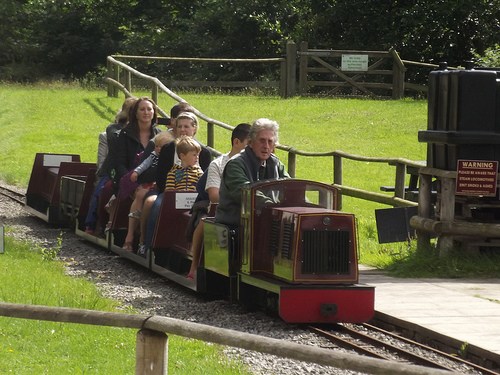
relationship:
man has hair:
[216, 118, 307, 225] [249, 117, 279, 146]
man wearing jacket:
[216, 118, 307, 225] [216, 150, 301, 220]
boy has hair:
[162, 136, 205, 192] [175, 136, 202, 159]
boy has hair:
[129, 132, 176, 182] [154, 131, 177, 148]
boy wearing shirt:
[129, 132, 176, 182] [134, 151, 162, 172]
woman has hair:
[145, 113, 214, 256] [175, 111, 199, 137]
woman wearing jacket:
[145, 113, 214, 256] [155, 140, 212, 194]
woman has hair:
[117, 98, 165, 177] [129, 97, 158, 132]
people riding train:
[83, 97, 291, 278] [22, 152, 375, 326]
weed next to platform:
[382, 232, 471, 280] [358, 276, 500, 370]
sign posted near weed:
[374, 206, 423, 253] [382, 232, 471, 280]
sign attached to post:
[374, 206, 423, 253] [403, 209, 414, 253]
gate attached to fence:
[296, 44, 402, 102] [105, 40, 499, 261]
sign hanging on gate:
[339, 53, 367, 73] [296, 44, 402, 102]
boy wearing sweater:
[162, 136, 205, 192] [166, 163, 204, 193]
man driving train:
[216, 118, 307, 225] [22, 152, 375, 326]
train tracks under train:
[303, 322, 499, 372] [22, 152, 375, 326]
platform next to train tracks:
[358, 276, 500, 370] [303, 322, 499, 372]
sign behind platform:
[454, 156, 499, 200] [358, 276, 500, 370]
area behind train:
[1, 85, 432, 274] [22, 152, 375, 326]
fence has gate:
[105, 40, 499, 261] [296, 44, 402, 102]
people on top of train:
[83, 97, 291, 278] [22, 152, 375, 326]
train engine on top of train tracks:
[240, 177, 377, 323] [303, 322, 499, 372]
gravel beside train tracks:
[0, 182, 500, 374] [303, 322, 499, 372]